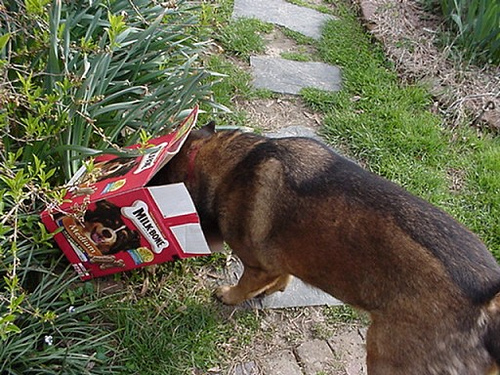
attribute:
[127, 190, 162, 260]
bone — white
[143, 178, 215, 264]
flap — red, white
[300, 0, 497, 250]
grass — green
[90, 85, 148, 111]
stems — dark green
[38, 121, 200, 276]
box — red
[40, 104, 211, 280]
cardboard box — red, white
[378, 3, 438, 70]
grass — dead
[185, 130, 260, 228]
neck — bent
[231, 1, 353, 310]
stepping stone — cement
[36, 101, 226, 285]
box — cardboard, red, white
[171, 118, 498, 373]
dog — brown, black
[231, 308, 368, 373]
stones — brick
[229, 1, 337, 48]
tile — stone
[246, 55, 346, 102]
tile — stone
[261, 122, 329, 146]
tile — stone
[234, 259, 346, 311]
tile — stone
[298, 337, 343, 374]
tile — stone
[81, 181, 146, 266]
head — dog's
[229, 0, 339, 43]
stepping stone — gray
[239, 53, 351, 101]
stepping stone — gray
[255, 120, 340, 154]
stepping stone — gray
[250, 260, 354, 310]
stepping stone — gray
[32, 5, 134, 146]
plants — green, tall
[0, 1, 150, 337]
leaves — green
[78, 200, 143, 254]
dog — picture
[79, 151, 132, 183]
dog — picture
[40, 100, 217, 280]
red/white box — red, white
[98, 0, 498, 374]
grass — green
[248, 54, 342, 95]
stone — gray, paving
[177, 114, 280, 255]
neck — furry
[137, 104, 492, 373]
dog — front legs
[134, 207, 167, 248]
lettering — black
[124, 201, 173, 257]
logo — Milk Bone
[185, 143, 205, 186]
belt — red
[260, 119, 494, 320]
streak — black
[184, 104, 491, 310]
back — dog's